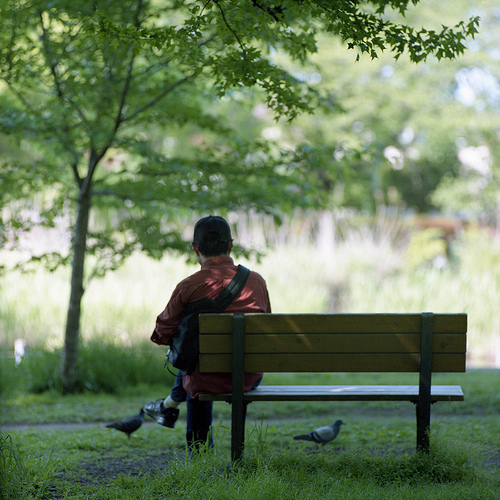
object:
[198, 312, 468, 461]
bench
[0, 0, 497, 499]
park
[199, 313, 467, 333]
piece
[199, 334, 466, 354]
piece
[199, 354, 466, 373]
piece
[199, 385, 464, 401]
seat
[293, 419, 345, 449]
bird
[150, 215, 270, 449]
man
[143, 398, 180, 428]
foot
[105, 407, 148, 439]
bird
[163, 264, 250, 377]
bag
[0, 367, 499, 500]
grass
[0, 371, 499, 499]
ground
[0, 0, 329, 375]
tree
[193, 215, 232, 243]
cap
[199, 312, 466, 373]
panels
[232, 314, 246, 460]
support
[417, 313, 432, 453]
support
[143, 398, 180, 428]
shoe